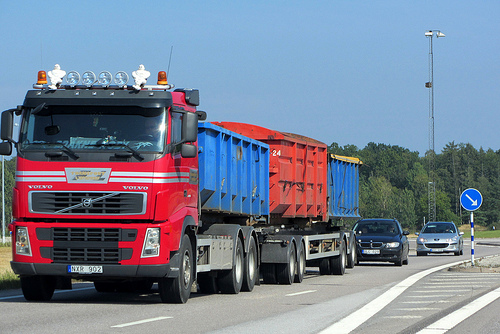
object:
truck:
[2, 62, 367, 303]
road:
[0, 239, 500, 333]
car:
[352, 216, 411, 264]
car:
[415, 220, 460, 256]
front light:
[384, 242, 401, 250]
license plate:
[362, 249, 379, 254]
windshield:
[359, 220, 399, 236]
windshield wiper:
[373, 230, 400, 235]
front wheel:
[160, 228, 197, 305]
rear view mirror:
[403, 228, 411, 237]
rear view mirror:
[172, 111, 198, 151]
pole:
[458, 187, 483, 265]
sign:
[458, 188, 485, 211]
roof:
[23, 66, 366, 165]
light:
[157, 71, 168, 86]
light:
[36, 69, 49, 86]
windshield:
[19, 104, 167, 157]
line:
[315, 253, 500, 333]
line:
[408, 284, 500, 333]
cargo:
[195, 123, 272, 222]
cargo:
[327, 154, 365, 219]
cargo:
[211, 121, 330, 221]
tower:
[424, 30, 446, 222]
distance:
[346, 0, 500, 230]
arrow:
[465, 192, 478, 208]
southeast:
[472, 202, 500, 255]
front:
[14, 91, 167, 267]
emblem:
[64, 168, 110, 186]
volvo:
[119, 181, 151, 193]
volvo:
[28, 183, 57, 190]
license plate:
[68, 263, 106, 274]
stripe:
[14, 169, 194, 179]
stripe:
[15, 175, 202, 185]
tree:
[359, 176, 417, 231]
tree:
[384, 160, 458, 224]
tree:
[434, 145, 499, 230]